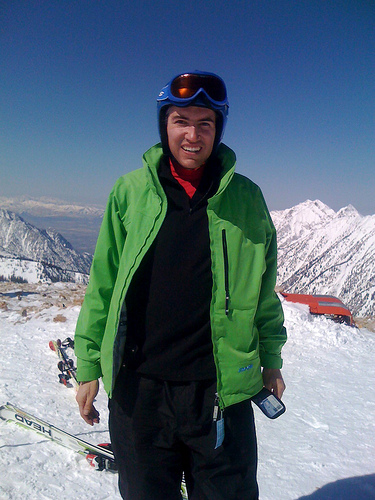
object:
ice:
[296, 206, 340, 264]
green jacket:
[75, 140, 285, 410]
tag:
[212, 402, 225, 447]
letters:
[239, 367, 252, 374]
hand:
[263, 366, 286, 401]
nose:
[185, 124, 200, 143]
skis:
[1, 0, 113, 79]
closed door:
[72, 173, 291, 388]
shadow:
[297, 473, 374, 497]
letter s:
[160, 92, 164, 95]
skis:
[0, 399, 115, 478]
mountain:
[267, 202, 373, 298]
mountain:
[1, 192, 91, 293]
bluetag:
[215, 418, 224, 450]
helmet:
[155, 68, 229, 144]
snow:
[0, 196, 375, 500]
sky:
[4, 2, 374, 199]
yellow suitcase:
[106, 377, 261, 496]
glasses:
[157, 71, 229, 108]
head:
[157, 70, 227, 172]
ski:
[1, 395, 117, 478]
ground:
[0, 153, 375, 497]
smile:
[180, 142, 204, 154]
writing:
[15, 412, 54, 438]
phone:
[253, 387, 285, 421]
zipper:
[112, 177, 232, 424]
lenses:
[202, 75, 226, 105]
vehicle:
[277, 291, 350, 327]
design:
[238, 364, 252, 372]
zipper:
[221, 229, 231, 313]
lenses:
[172, 74, 198, 101]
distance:
[5, 194, 373, 263]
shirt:
[113, 169, 234, 415]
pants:
[108, 361, 268, 498]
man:
[73, 67, 286, 500]